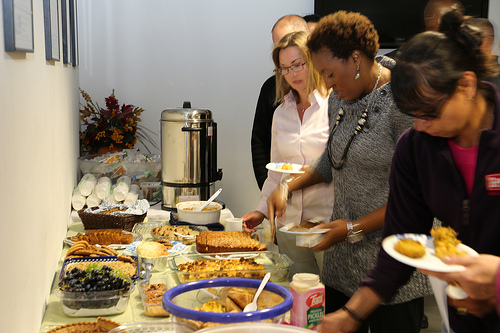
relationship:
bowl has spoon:
[162, 274, 294, 329] [241, 266, 274, 317]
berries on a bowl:
[96, 280, 104, 286] [57, 248, 137, 317]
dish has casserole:
[173, 197, 224, 227] [184, 203, 219, 211]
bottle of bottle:
[289, 270, 332, 330] [289, 272, 327, 332]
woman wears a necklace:
[269, 8, 438, 329] [322, 61, 382, 172]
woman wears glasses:
[240, 31, 352, 281] [273, 57, 310, 77]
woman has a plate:
[269, 8, 438, 329] [278, 212, 335, 238]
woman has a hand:
[269, 8, 438, 329] [311, 214, 353, 254]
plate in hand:
[278, 212, 335, 238] [311, 214, 353, 254]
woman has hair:
[240, 31, 352, 281] [271, 29, 329, 103]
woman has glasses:
[240, 31, 352, 281] [273, 57, 310, 77]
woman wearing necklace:
[269, 8, 438, 329] [322, 61, 382, 172]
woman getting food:
[269, 8, 438, 329] [46, 188, 321, 332]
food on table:
[46, 188, 321, 332] [47, 161, 320, 331]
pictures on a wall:
[1, 0, 82, 67] [0, 1, 84, 332]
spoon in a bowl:
[241, 266, 274, 317] [162, 274, 294, 329]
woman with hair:
[321, 5, 499, 332] [386, 5, 489, 122]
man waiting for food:
[248, 13, 313, 191] [46, 188, 321, 332]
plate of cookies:
[59, 243, 137, 257] [63, 237, 123, 258]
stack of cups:
[67, 170, 141, 213] [70, 171, 143, 212]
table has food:
[47, 161, 320, 331] [46, 188, 321, 332]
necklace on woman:
[322, 61, 382, 172] [269, 8, 438, 329]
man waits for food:
[248, 13, 313, 191] [46, 188, 321, 332]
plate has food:
[379, 226, 481, 276] [392, 222, 468, 262]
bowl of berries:
[57, 248, 137, 317] [96, 280, 104, 286]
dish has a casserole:
[173, 197, 224, 227] [184, 203, 219, 211]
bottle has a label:
[289, 272, 327, 332] [305, 289, 328, 329]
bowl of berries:
[52, 277, 136, 317] [60, 264, 126, 296]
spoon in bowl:
[241, 266, 274, 317] [162, 276, 294, 332]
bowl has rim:
[162, 276, 294, 332] [162, 276, 295, 324]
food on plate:
[292, 215, 330, 231] [278, 212, 335, 238]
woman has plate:
[269, 8, 438, 329] [278, 212, 335, 238]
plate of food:
[278, 212, 335, 238] [292, 215, 330, 231]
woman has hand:
[269, 8, 438, 329] [311, 214, 353, 254]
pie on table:
[43, 313, 117, 332] [47, 161, 320, 331]